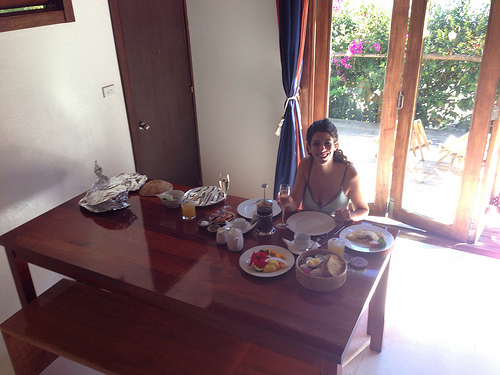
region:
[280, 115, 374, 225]
Woman sitting at table.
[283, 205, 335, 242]
Empty white plate in front of woman.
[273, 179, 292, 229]
Woman holding glass of wine in hand.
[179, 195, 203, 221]
Glass of orange juice sitting on table.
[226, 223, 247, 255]
White tea pot sitting on table.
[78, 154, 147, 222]
Aluminum foil lying on table.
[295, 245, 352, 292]
Basket holding food sitting on table.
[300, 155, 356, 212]
Woman dressed in gray and black tank top.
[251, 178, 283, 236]
French coffee press sitting on table.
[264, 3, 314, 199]
Curtain hanging at French doors.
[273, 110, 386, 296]
a woman eating a meal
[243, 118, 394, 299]
a woman sitting in front of several plates of food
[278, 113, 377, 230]
a woman drinking a glass of white wine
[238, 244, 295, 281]
a plate of colorful food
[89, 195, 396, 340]
a table covered with food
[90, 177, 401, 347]
a wooden table covered with food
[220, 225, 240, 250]
a small white tea pitcher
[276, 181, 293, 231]
a glass of white wine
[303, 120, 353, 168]
a woman with black hair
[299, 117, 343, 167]
a woman who is smiling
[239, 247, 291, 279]
White plate of fruit on table.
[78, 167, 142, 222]
Aluminum foil folded on table.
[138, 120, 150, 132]
Silver door handle.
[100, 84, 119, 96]
Wall electrical light switch.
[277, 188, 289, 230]
Glass of pink wine.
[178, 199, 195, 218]
Glass of orange juice.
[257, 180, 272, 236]
Pepper grinder on table.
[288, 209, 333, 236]
Empty white plate on table.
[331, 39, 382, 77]
Purple flowers on bushes.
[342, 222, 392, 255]
White plate of food on table.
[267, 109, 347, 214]
a woman holding a wine glass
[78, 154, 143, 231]
a piece of tin foil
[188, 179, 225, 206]
a black and white plate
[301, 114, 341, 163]
a woman with dark hair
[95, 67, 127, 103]
a white light switch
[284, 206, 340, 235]
a white plate on a table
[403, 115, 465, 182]
patio furniture on a porch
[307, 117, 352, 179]
a woman with long hair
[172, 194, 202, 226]
a glass of orange juice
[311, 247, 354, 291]
pieces of bread in a bowl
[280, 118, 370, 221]
Woman with brown hair in light grey tank top.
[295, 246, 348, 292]
Tan bowl of sliced bread.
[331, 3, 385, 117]
Pink flowers on tree shrub.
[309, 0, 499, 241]
Double glass doors lined with wood.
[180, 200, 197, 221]
Small glass of orange juice.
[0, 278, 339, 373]
Dark brown wood bench.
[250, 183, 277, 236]
Small French coffee press.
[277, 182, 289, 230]
Tall glass of champagne.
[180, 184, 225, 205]
Plate covered with tin foil.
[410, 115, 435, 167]
Light wood deck chair.